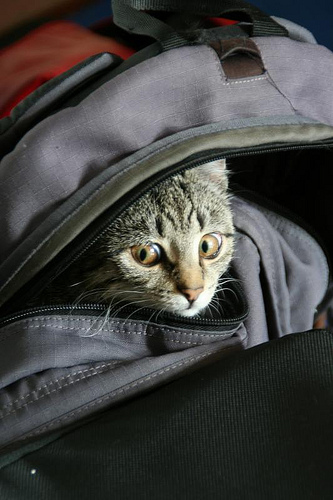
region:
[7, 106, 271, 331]
a crazy cat in a back pack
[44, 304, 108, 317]
a black zipper on a back pack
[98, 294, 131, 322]
white whiskers on a mouth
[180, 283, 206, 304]
a small pink nose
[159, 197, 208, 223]
soft gray fur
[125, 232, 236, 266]
bright orange-green eyes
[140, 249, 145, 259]
a black diamond shaped pupil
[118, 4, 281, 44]
a black strap on the backpack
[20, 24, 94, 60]
a red patch on the back pack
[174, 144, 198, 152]
gray lining in the backpack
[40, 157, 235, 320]
gray tabby kitten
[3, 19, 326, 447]
small cat in a gray bag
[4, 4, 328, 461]
unzipped gray bag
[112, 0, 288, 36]
black handle of the bag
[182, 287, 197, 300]
nose of the kitten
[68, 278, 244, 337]
The kitten's white whiskers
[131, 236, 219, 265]
two cat eyes looking to the cat's right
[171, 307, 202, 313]
the kitten's tiny mouth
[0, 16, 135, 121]
red bag behind the gray bag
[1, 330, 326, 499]
black bag in front of the gray bag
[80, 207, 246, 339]
cat inside of bag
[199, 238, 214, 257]
pupil in cat's eye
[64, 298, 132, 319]
zipper on edge of bag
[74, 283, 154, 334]
whiskers on cat's face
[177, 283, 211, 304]
nose on cat's face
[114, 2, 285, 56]
black handle on bag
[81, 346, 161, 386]
thread in blue material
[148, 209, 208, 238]
stripes on cat head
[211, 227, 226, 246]
whites of cat's eye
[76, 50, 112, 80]
light reflection on plastic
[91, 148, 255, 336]
A cat peeking it's head.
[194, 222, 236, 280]
a cat's left eye.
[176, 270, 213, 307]
a cat's nose.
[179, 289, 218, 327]
the mouth of a cat.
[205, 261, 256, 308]
whiskers on a cat.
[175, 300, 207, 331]
a cat's small mouth.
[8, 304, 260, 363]
a zipper on a jacket.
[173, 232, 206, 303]
a nose on a cat.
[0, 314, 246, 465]
a gray piece of baggage.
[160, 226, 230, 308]
A section of a cat's face.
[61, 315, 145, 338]
grey stitching on grey bag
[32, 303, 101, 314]
black zipper on grey bag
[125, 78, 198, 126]
grey textured material of bag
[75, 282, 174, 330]
long whiskers of a cat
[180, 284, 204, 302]
pink butterfly shaped nose of cat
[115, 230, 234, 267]
golden brown and black cat eyes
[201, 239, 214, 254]
reflection of light in eye iris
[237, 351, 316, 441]
black ribbed upholstery material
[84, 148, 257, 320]
cat peeking out of travel bag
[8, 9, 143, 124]
red object behind travel bag